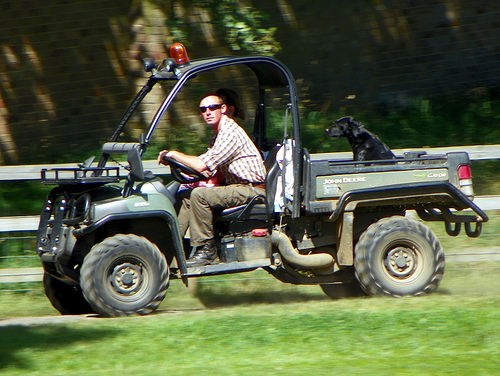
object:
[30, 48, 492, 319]
vehicle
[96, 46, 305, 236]
frame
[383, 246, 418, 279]
rim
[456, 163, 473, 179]
head light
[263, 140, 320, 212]
jacket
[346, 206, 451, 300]
wheel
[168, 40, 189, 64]
light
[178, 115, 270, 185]
man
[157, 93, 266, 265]
man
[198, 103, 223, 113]
sunglasses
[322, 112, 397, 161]
dog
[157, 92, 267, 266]
human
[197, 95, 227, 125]
head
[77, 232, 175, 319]
front tire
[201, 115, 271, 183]
shirt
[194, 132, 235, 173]
sleeve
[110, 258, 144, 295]
rim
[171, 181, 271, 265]
pants